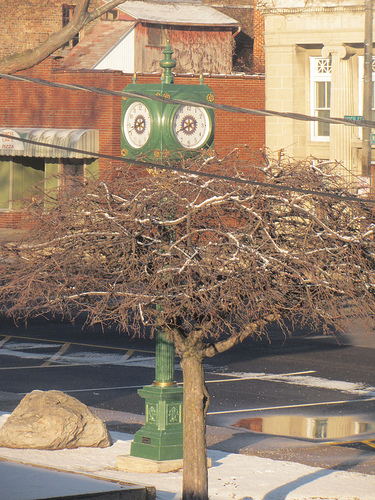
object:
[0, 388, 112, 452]
rock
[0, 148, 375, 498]
tree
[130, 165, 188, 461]
pole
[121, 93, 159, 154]
clock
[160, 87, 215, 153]
clock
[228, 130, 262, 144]
bricks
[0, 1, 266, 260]
building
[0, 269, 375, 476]
street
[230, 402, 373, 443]
puddle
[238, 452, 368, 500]
shadow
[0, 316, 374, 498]
area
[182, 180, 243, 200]
snow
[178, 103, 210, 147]
face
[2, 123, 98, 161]
awning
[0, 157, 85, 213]
window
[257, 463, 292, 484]
snow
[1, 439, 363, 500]
ground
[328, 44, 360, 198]
pillar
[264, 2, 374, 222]
building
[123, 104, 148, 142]
face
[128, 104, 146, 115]
numbers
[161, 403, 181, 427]
design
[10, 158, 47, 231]
entrance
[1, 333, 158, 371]
lines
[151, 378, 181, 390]
ring